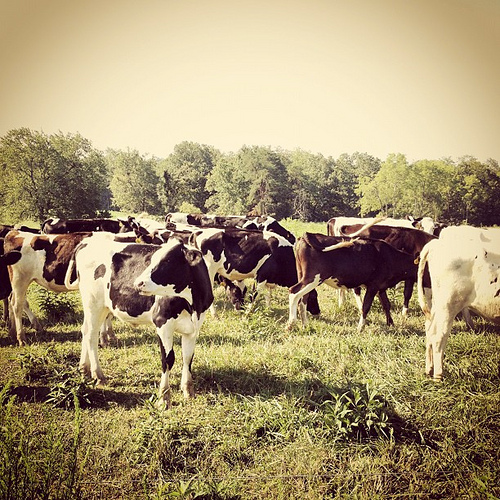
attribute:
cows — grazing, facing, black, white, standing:
[0, 224, 499, 406]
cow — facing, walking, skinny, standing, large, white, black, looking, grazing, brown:
[69, 228, 216, 421]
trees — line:
[10, 118, 499, 223]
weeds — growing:
[331, 384, 404, 449]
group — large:
[320, 202, 498, 359]